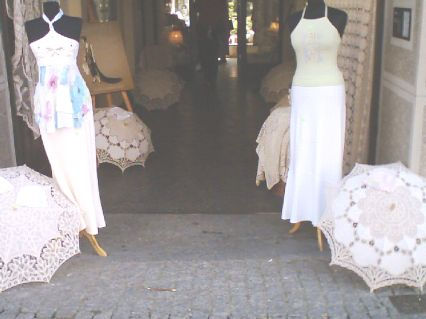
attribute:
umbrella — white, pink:
[0, 163, 82, 292]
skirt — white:
[280, 68, 359, 241]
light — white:
[170, 23, 185, 49]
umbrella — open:
[0, 154, 91, 296]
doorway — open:
[162, 1, 282, 72]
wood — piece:
[79, 229, 106, 257]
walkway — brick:
[2, 209, 401, 317]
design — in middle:
[44, 70, 59, 93]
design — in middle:
[68, 83, 88, 116]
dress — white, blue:
[285, 14, 342, 246]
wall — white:
[307, 0, 370, 213]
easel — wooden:
[72, 19, 135, 122]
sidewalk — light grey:
[164, 155, 248, 289]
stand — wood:
[58, 46, 137, 97]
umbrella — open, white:
[92, 104, 157, 172]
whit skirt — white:
[36, 109, 108, 235]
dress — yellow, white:
[278, 4, 346, 227]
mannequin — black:
[283, 0, 360, 244]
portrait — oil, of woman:
[79, 20, 137, 94]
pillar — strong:
[233, 0, 247, 92]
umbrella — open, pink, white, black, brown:
[319, 161, 426, 293]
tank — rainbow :
[30, 10, 92, 130]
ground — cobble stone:
[19, 290, 352, 312]